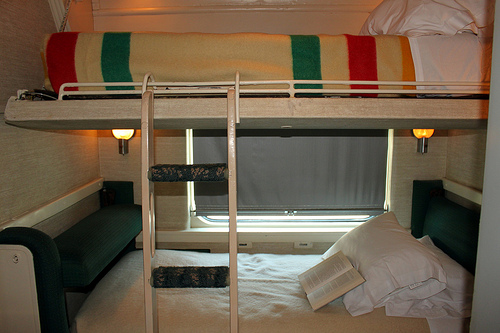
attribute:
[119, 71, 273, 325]
ladder — metal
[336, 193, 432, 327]
pillows — white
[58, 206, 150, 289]
pillows — green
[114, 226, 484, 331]
pillows — white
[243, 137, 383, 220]
shade — gray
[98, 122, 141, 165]
light — bright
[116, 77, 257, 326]
ladder — white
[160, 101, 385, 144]
blanket — striped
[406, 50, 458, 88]
sheet — white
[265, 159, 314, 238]
shade — grey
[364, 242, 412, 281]
pillow — white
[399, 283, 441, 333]
pillow — white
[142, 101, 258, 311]
ladder — wooden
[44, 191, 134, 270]
headrest — green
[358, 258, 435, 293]
pillow — white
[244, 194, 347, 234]
blind — gray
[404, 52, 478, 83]
sheet — white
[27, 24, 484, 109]
mattress — multicolored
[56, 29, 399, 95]
sheets — yellow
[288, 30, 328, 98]
stripe — green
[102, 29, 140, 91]
stripe — green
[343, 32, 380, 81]
stripe — red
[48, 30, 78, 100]
stripe — red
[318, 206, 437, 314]
pillow — white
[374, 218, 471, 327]
pillow — white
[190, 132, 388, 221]
shade — gray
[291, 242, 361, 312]
book — open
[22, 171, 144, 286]
cushion — green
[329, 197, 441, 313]
pillow sheet — white